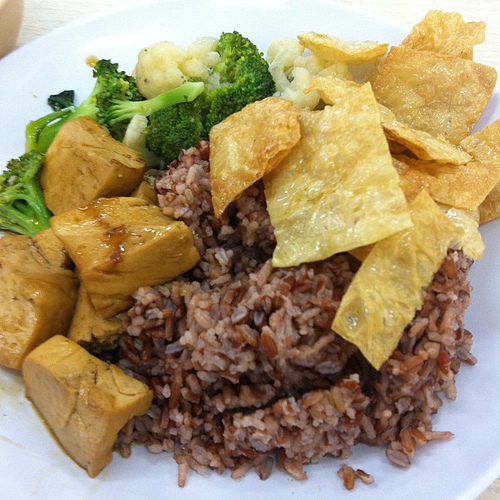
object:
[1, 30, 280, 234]
broccoli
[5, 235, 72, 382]
chunk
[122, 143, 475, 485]
pile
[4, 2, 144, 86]
table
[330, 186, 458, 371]
chip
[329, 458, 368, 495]
pieces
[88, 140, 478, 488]
rice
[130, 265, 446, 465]
rice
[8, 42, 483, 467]
food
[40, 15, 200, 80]
white plate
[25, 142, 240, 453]
meat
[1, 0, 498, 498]
plate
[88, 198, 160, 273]
sauce